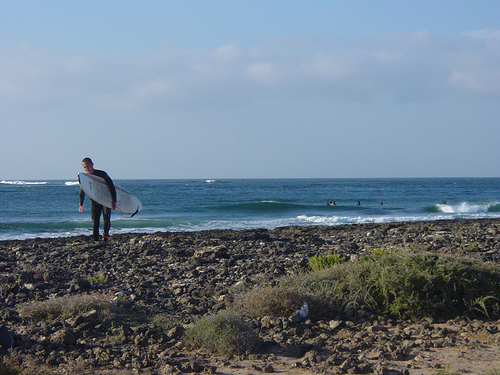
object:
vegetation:
[235, 248, 500, 317]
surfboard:
[75, 170, 144, 214]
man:
[75, 156, 120, 239]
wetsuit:
[76, 170, 117, 239]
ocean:
[0, 177, 500, 245]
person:
[354, 200, 361, 207]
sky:
[1, 2, 499, 181]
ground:
[1, 217, 498, 375]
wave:
[0, 198, 499, 231]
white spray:
[435, 201, 489, 217]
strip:
[79, 168, 136, 195]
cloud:
[0, 22, 499, 119]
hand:
[110, 199, 118, 209]